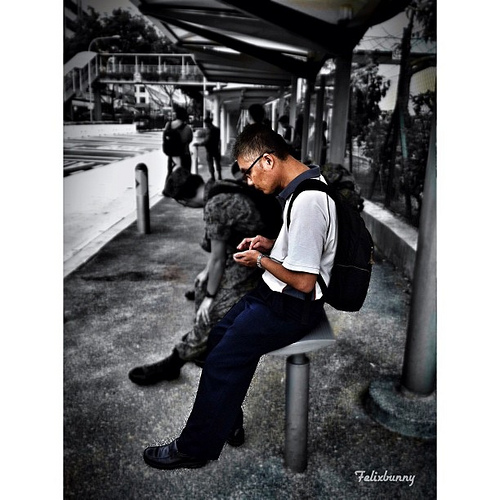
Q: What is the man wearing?
A: Clothes.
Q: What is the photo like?
A: Edited.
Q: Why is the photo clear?
A: Its during the day.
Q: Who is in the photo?
A: People.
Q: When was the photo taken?
A: Daytime.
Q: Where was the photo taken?
A: At a bus stop.